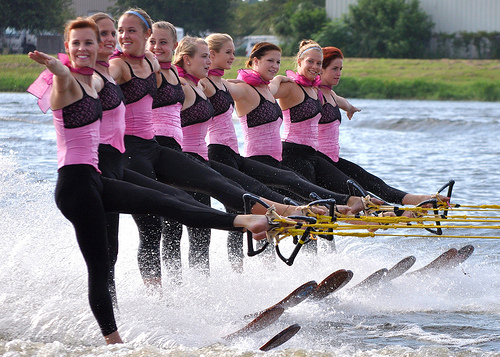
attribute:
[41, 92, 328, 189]
blouses — pink, white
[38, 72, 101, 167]
tank top — pink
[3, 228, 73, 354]
water — splashing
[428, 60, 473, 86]
grass — green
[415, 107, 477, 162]
water — white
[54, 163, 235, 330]
pants — black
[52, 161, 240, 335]
leggings — black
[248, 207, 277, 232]
foot — woman's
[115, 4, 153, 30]
scarf — blue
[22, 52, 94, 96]
scarf — pink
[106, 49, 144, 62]
scarf — pink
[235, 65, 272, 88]
scarf — pink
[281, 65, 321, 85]
scarf — pink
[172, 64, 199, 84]
scarf — pink